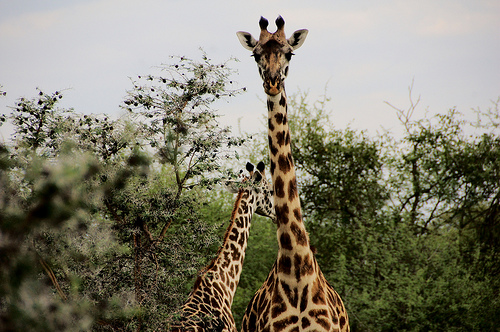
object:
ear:
[253, 171, 263, 184]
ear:
[236, 30, 256, 50]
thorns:
[101, 224, 151, 332]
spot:
[275, 203, 290, 225]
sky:
[10, 2, 497, 223]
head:
[235, 15, 308, 96]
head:
[237, 160, 277, 220]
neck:
[265, 102, 303, 265]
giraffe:
[232, 16, 348, 331]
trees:
[395, 110, 500, 232]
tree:
[291, 119, 391, 311]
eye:
[282, 51, 294, 63]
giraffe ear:
[290, 28, 309, 49]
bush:
[402, 130, 493, 253]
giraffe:
[156, 159, 269, 331]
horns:
[275, 14, 285, 32]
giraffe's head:
[229, 15, 351, 332]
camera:
[87, 90, 388, 278]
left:
[153, 145, 200, 259]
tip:
[74, 110, 178, 223]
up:
[79, 100, 131, 217]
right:
[317, 114, 377, 231]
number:
[154, 81, 372, 290]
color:
[58, 223, 159, 332]